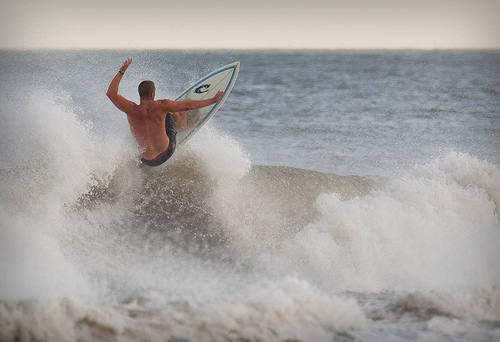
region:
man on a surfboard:
[82, 48, 257, 178]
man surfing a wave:
[73, 48, 257, 194]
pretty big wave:
[3, 73, 495, 340]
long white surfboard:
[158, 60, 252, 160]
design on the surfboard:
[195, 81, 211, 93]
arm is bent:
[103, 53, 135, 108]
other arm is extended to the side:
[169, 86, 231, 114]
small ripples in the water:
[291, 88, 370, 138]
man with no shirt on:
[98, 41, 234, 178]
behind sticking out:
[133, 147, 188, 171]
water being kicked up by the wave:
[17, 74, 92, 166]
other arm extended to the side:
[157, 88, 242, 120]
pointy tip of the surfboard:
[231, 51, 246, 77]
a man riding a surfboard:
[85, 30, 247, 189]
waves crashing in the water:
[272, 121, 498, 322]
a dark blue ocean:
[262, 48, 467, 157]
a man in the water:
[65, 42, 257, 173]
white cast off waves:
[0, 215, 164, 310]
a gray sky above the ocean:
[182, 11, 397, 45]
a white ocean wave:
[247, 147, 434, 304]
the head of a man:
[127, 77, 173, 108]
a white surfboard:
[124, 53, 266, 188]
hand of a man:
[109, 53, 141, 81]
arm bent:
[98, 53, 140, 116]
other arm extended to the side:
[166, 89, 232, 108]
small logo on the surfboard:
[191, 78, 213, 94]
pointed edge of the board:
[223, 53, 251, 71]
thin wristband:
[114, 68, 126, 76]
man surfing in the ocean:
[59, 33, 261, 204]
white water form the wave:
[13, 88, 105, 240]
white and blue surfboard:
[147, 57, 232, 149]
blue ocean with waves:
[290, 48, 392, 168]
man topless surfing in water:
[87, 54, 201, 159]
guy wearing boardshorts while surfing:
[135, 112, 187, 184]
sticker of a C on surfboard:
[182, 75, 218, 106]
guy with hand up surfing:
[72, 56, 284, 202]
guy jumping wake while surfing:
[89, 32, 276, 221]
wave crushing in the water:
[168, 148, 379, 316]